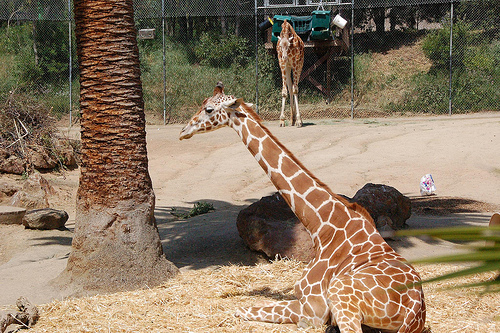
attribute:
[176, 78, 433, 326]
giraffe — healthy, tired, relaxing, tall, big, attractive, laying, looking, sitting, facing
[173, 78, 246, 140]
head — giraffe's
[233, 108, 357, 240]
neck — giraffe's, long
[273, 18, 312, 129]
giraffe — standing, walking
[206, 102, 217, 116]
eye — giraffe's, open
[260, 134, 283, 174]
spot — brown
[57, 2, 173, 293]
trunk — tree, brown, large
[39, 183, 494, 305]
shadow — tree, tree's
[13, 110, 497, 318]
ground — dirt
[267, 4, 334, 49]
something — blue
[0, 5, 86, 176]
pile — brush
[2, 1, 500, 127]
fence — metal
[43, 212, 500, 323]
grass — straw, yellow, brown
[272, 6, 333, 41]
object — green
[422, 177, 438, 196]
bag — paper, white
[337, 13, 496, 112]
leaves — showing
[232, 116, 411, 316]
spots — brown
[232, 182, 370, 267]
rock — big, boulder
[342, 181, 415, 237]
rock — boulder, big